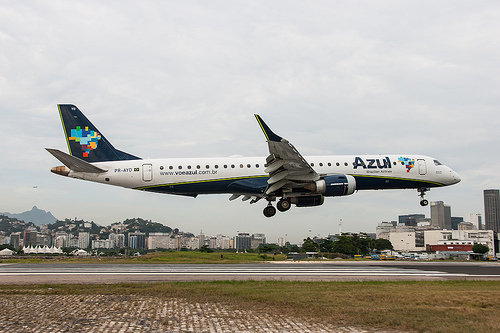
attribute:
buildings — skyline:
[386, 193, 497, 263]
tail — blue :
[58, 104, 142, 162]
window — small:
[165, 162, 178, 174]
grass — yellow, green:
[230, 277, 497, 330]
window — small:
[187, 164, 192, 169]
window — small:
[203, 155, 227, 174]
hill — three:
[107, 217, 182, 231]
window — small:
[172, 159, 185, 170]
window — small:
[194, 161, 203, 174]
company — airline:
[347, 152, 403, 177]